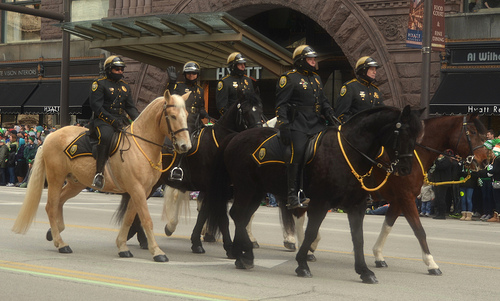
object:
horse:
[9, 88, 204, 263]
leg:
[128, 186, 171, 262]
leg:
[45, 161, 75, 253]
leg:
[294, 191, 332, 277]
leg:
[347, 207, 381, 283]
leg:
[227, 172, 260, 269]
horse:
[365, 98, 494, 275]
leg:
[399, 191, 444, 277]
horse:
[198, 99, 436, 285]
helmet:
[355, 55, 384, 73]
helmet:
[289, 43, 317, 61]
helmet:
[224, 50, 249, 66]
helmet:
[104, 54, 129, 70]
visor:
[370, 63, 383, 68]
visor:
[237, 61, 248, 65]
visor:
[187, 71, 197, 75]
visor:
[114, 68, 124, 71]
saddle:
[61, 129, 125, 160]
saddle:
[244, 128, 326, 166]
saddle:
[158, 124, 206, 158]